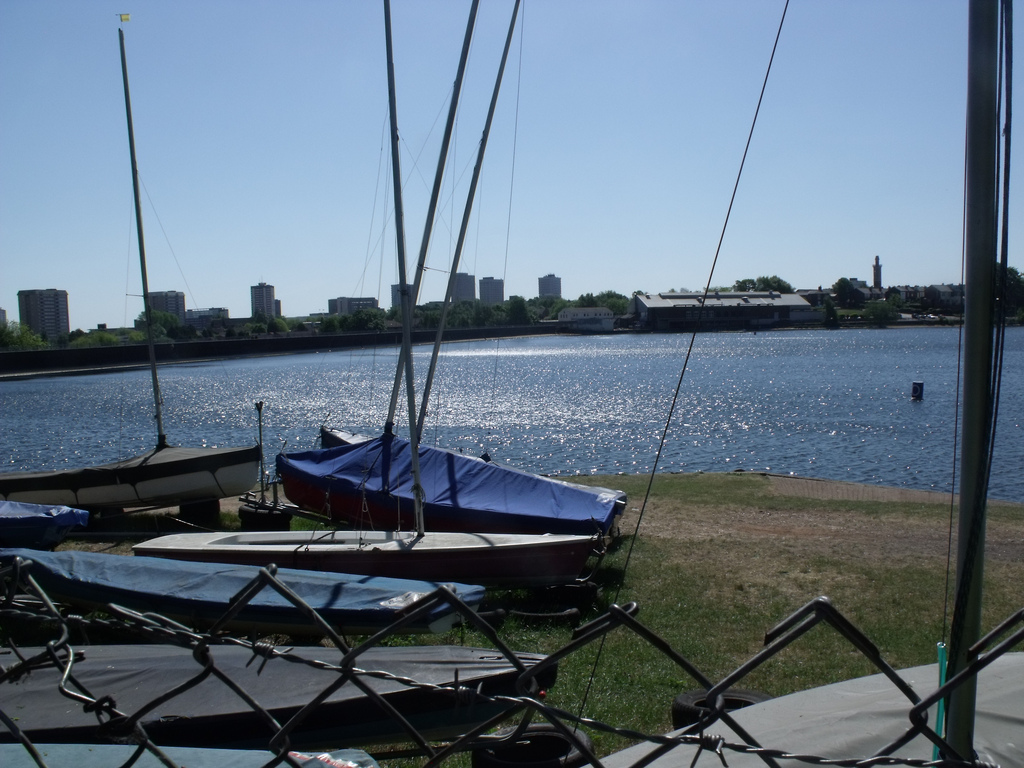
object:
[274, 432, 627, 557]
boat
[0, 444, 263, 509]
boat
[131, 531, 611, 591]
boat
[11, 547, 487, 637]
boat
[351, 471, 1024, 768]
grass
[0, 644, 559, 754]
boat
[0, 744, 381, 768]
boat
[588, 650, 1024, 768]
boat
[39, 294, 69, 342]
wall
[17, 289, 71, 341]
building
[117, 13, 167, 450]
mast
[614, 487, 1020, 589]
dirt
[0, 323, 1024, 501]
water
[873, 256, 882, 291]
steeple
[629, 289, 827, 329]
building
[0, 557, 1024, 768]
barbed wire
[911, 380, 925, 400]
buoy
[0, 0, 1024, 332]
clouds